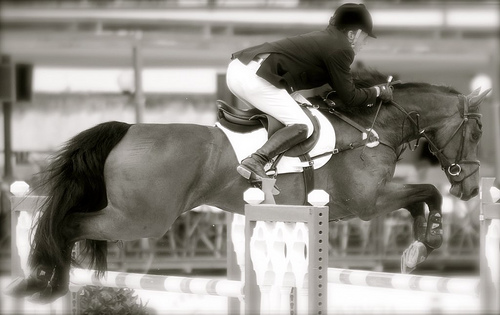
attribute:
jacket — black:
[230, 29, 380, 117]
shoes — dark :
[239, 122, 307, 181]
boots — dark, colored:
[238, 119, 317, 182]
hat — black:
[329, 1, 376, 38]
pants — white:
[183, 50, 394, 200]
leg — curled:
[362, 184, 442, 266]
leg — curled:
[402, 200, 428, 274]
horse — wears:
[3, 80, 492, 302]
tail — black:
[12, 119, 129, 296]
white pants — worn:
[224, 62, 333, 169]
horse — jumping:
[24, 84, 486, 287]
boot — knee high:
[236, 122, 311, 184]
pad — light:
[215, 87, 337, 177]